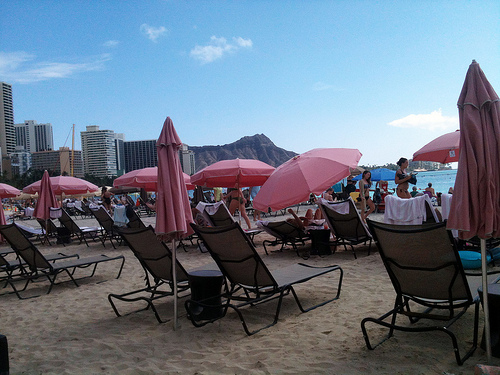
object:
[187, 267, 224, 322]
container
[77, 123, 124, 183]
tall building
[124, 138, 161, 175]
tall building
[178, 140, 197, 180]
tall building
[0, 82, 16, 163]
tall building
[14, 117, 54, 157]
tall building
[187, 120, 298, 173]
mountain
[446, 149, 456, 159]
number tag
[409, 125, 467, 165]
umbrella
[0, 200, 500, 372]
sand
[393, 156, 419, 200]
woman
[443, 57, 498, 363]
closed umbrella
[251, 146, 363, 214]
umbrella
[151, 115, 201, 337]
umbrella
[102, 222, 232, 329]
chair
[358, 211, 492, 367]
chair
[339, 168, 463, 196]
water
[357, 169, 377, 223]
woman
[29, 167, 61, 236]
umbrella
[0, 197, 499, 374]
beach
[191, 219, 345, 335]
lounge chair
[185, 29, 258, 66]
cloud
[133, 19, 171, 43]
cloud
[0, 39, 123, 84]
cloud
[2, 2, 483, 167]
sky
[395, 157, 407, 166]
hair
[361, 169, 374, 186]
hair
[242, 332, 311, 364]
foot prints